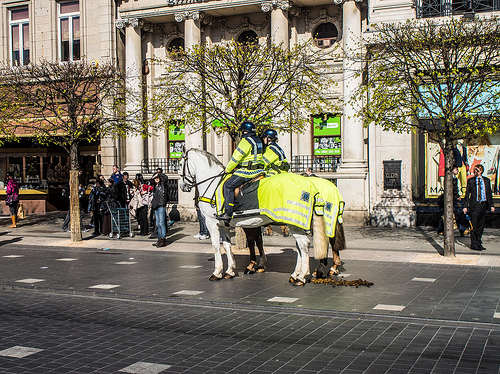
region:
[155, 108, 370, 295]
Police officers on horses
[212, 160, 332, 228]
Yellow blanket on a horse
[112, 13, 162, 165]
Stone column in front of building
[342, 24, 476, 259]
Small tree growing on sidewalk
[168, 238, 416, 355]
Black and white city street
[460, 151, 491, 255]
Man in suit on sidewalk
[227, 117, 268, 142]
Helmet on a police officer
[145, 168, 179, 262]
Person wearing jeans standing on sidewalk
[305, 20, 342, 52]
Round window on front of building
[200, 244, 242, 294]
Hooves on a white horse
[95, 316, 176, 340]
bricks on the street.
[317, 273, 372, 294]
horse droppings on the ground.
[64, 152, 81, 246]
trunk of the tree.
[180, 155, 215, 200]
white horse on the street.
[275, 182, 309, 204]
reflective vest on horse.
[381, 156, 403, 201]
plaque on the wall.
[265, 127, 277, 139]
helmet on person's head.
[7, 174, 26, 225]
woman on the sidewalk.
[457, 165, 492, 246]
man in a suit.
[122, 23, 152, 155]
pillar in front of building.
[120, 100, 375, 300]
two mounted police officers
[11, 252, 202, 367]
black and white tile sidewalk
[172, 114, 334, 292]
white police horse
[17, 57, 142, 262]
tree with a few leaves on it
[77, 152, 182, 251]
group of people standing on a sidewalk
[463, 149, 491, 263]
man wearing a business suit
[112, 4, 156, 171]
ionic style column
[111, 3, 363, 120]
edifice of building with columns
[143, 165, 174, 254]
pedestrian wearing leather jacket and blue jeans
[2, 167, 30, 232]
pedestrian wearing purple sweater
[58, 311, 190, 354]
small black tiles on street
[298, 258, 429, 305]
horse poo on street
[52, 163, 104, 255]
brown base of large tree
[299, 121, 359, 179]
green cover in window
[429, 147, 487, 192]
mannequin with red dress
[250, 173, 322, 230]
yellow cover on horse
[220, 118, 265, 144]
shiny blue helmet on cop's head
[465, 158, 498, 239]
man turning around and looking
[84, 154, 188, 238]
people standing on the side walk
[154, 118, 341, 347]
horses standing on street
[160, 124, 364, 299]
Two horses are being ridden.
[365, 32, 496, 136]
The trees are blooming.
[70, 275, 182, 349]
The street is black.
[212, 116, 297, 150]
The people are wearing helmets.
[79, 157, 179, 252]
A group of people on the sidewalk.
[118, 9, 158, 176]
A stone pillar on the building.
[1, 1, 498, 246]
Buildings are in the background.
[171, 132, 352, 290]
The horse is white.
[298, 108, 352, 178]
Green signs are in the window.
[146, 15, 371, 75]
Round windows are in the building.